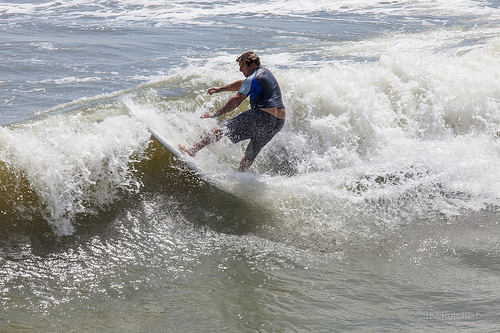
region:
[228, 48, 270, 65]
Man has dark hair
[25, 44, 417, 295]
Man surfing in ocean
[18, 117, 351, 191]
White cap on wave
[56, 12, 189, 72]
Ocean is blue in color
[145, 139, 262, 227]
Man's surfboard is white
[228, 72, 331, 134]
Man's shirt is blue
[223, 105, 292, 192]
Man is wearing dark shorts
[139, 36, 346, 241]
Man is in water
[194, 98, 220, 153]
Blue bracelet around man's wrist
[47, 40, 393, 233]
Waves in water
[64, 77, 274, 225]
This is a white surfboard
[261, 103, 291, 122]
This is a back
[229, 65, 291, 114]
This is a blue shirt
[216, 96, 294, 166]
These are blue shorts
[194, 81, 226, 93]
This is a right hand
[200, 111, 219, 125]
a wet left hand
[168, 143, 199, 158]
a wet left foot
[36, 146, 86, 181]
This is ocean spray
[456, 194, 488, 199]
This is white foam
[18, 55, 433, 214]
This is a wave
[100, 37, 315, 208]
surfer facing into a wave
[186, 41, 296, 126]
arms extended in front of body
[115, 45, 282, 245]
surfboard lifted over wave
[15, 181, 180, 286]
water glistening in sunlight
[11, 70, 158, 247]
white water falling over wave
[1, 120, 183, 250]
yellowish water under wave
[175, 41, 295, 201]
surfer curved forward on back of board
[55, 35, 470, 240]
higher water in back of wave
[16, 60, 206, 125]
line of water behind wave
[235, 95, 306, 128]
skin exposed on back of surfer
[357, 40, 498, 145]
White foam in the ocean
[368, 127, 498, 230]
White foam in the ocean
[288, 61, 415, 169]
White foam in the ocean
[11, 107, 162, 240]
White foam in the ocean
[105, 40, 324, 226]
Man surfing on white board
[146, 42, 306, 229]
Man surfing in the ocean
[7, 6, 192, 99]
Blue calm ocean water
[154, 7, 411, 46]
Blue calm ocean water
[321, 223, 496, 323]
Gray colored ocean water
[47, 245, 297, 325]
Gray colored ocean water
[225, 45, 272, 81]
Man has brown hair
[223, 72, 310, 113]
Man wearing blue shirt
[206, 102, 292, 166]
Man wearing dark shorts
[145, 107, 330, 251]
Man surfing in water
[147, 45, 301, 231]
Man on white surfboard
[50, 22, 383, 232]
Wave rolling in shore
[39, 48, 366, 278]
White cap on top of wave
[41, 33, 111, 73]
Water is blue beyond wave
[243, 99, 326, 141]
Man's skin is showing between shirt and shorts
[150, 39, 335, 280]
Man is surfing the wave